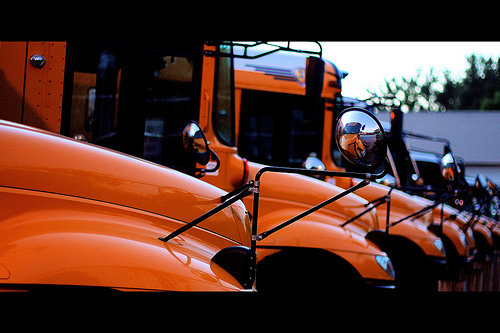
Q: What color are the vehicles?
A: Orange.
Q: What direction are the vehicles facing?
A: Right.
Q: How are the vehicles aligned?
A: In a row.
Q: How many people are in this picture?
A: None.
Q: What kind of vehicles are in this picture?
A: Buses.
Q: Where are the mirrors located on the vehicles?
A: On the side.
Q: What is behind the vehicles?
A: Trees.